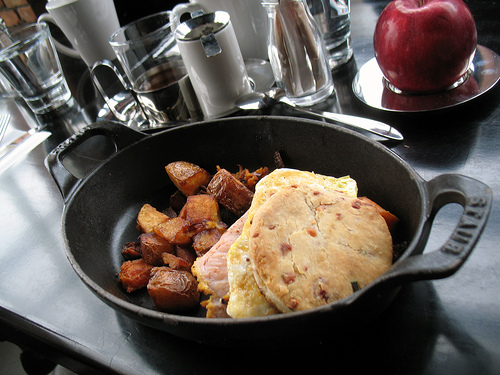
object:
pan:
[42, 116, 493, 323]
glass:
[1, 22, 73, 115]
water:
[1, 30, 71, 115]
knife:
[282, 96, 403, 140]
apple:
[372, 0, 477, 91]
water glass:
[106, 10, 205, 125]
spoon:
[233, 92, 277, 110]